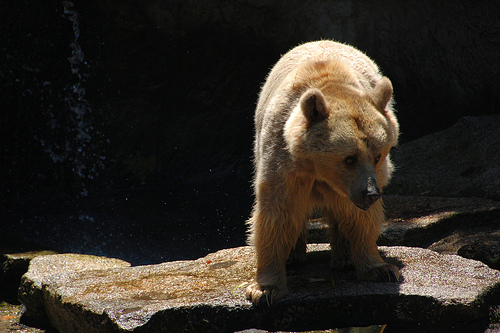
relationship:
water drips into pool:
[25, 0, 115, 250] [11, 239, 250, 271]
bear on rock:
[237, 38, 406, 311] [20, 242, 499, 332]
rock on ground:
[20, 242, 499, 332] [3, 278, 498, 331]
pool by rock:
[11, 239, 250, 271] [20, 242, 499, 332]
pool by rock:
[11, 239, 250, 271] [3, 246, 59, 308]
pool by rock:
[11, 239, 250, 271] [299, 111, 499, 204]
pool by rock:
[11, 239, 250, 271] [292, 189, 499, 249]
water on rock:
[25, 0, 115, 250] [3, 246, 59, 308]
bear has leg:
[237, 38, 406, 311] [241, 167, 316, 308]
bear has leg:
[237, 38, 406, 311] [325, 186, 405, 286]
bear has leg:
[237, 38, 406, 311] [323, 212, 357, 276]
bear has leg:
[237, 38, 406, 311] [290, 231, 310, 266]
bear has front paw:
[237, 38, 406, 311] [365, 260, 405, 284]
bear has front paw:
[237, 38, 406, 311] [244, 281, 289, 310]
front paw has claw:
[365, 260, 405, 284] [385, 269, 394, 285]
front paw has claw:
[244, 281, 289, 310] [269, 286, 279, 305]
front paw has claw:
[244, 281, 289, 310] [263, 289, 273, 310]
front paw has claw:
[365, 260, 405, 284] [389, 265, 402, 285]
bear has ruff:
[237, 38, 406, 311] [283, 80, 396, 191]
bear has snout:
[237, 38, 406, 311] [347, 174, 381, 213]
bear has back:
[237, 38, 406, 311] [253, 39, 392, 111]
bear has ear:
[237, 38, 406, 311] [367, 74, 394, 111]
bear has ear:
[237, 38, 406, 311] [299, 87, 330, 126]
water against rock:
[25, 0, 115, 250] [20, 242, 499, 333]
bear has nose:
[237, 38, 406, 311] [363, 183, 383, 203]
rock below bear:
[20, 242, 499, 332] [237, 38, 406, 311]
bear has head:
[237, 38, 406, 311] [283, 75, 398, 213]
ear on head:
[367, 74, 394, 111] [283, 75, 398, 213]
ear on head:
[299, 87, 330, 126] [283, 75, 398, 213]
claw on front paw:
[389, 265, 402, 285] [365, 260, 405, 284]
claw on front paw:
[385, 269, 394, 285] [365, 260, 405, 284]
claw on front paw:
[269, 286, 279, 305] [244, 281, 289, 310]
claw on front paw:
[263, 289, 273, 310] [244, 281, 289, 310]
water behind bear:
[25, 0, 115, 250] [237, 38, 406, 311]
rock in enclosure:
[20, 242, 499, 332] [2, 1, 499, 332]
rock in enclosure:
[299, 111, 499, 204] [2, 1, 499, 332]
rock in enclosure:
[292, 189, 499, 249] [2, 1, 499, 332]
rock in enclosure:
[3, 246, 59, 308] [2, 1, 499, 332]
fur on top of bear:
[294, 57, 381, 129] [237, 38, 406, 311]